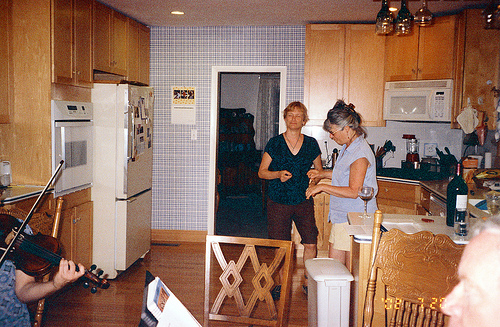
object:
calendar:
[168, 84, 195, 125]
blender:
[400, 132, 424, 166]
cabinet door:
[303, 20, 344, 124]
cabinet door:
[345, 24, 388, 125]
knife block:
[438, 147, 458, 187]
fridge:
[94, 81, 155, 282]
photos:
[132, 88, 151, 156]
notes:
[127, 86, 156, 163]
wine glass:
[455, 203, 472, 238]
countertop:
[350, 210, 488, 242]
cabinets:
[98, 10, 153, 85]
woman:
[258, 99, 323, 289]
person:
[2, 206, 88, 325]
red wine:
[361, 193, 371, 202]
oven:
[50, 97, 90, 193]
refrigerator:
[87, 82, 150, 272]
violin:
[0, 215, 110, 295]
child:
[0, 211, 92, 326]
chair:
[204, 236, 293, 325]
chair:
[360, 211, 468, 326]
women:
[258, 102, 384, 278]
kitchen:
[1, 0, 496, 325]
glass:
[355, 185, 373, 221]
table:
[350, 206, 483, 243]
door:
[215, 69, 289, 248]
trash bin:
[302, 254, 351, 324]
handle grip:
[127, 108, 139, 167]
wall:
[8, 4, 500, 286]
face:
[327, 123, 354, 145]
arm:
[306, 156, 370, 198]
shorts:
[325, 215, 378, 249]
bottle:
[444, 159, 471, 230]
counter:
[376, 206, 496, 281]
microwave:
[382, 79, 458, 119]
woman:
[312, 98, 381, 282]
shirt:
[323, 136, 377, 220]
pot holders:
[451, 99, 479, 146]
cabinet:
[305, 9, 497, 131]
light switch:
[189, 128, 200, 142]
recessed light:
[165, 6, 187, 19]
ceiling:
[123, 0, 305, 25]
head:
[283, 102, 310, 131]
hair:
[282, 99, 310, 121]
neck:
[282, 123, 301, 144]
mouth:
[291, 119, 303, 126]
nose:
[291, 114, 298, 123]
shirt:
[262, 131, 322, 202]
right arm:
[257, 148, 294, 188]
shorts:
[263, 197, 322, 248]